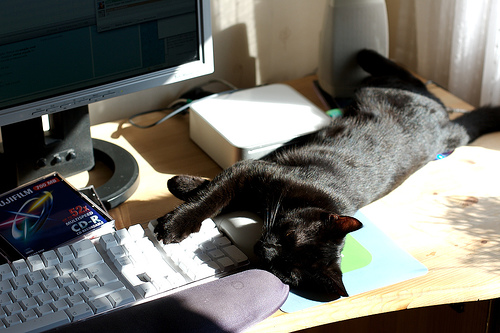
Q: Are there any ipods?
A: No, there are no ipods.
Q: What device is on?
A: The device is a monitor.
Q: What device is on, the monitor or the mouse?
A: The monitor is on.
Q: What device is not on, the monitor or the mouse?
A: The mouse is not on.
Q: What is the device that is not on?
A: The device is a computer mouse.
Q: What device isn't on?
A: The device is a computer mouse.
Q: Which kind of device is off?
A: The device is a monitor.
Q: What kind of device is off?
A: The device is a monitor.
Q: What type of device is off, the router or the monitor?
A: The monitor is off.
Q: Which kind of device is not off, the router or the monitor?
A: The router is not off.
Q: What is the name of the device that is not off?
A: The device is a router.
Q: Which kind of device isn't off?
A: The device is a router.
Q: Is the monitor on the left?
A: Yes, the monitor is on the left of the image.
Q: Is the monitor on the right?
A: No, the monitor is on the left of the image.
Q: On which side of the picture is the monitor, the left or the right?
A: The monitor is on the left of the image.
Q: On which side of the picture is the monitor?
A: The monitor is on the left of the image.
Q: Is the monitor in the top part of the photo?
A: Yes, the monitor is in the top of the image.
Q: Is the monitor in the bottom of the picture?
A: No, the monitor is in the top of the image.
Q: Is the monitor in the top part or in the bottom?
A: The monitor is in the top of the image.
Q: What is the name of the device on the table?
A: The device is a monitor.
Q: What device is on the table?
A: The device is a monitor.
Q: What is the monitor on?
A: The monitor is on the table.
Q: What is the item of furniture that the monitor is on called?
A: The piece of furniture is a table.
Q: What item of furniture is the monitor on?
A: The monitor is on the table.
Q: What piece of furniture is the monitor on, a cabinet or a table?
A: The monitor is on a table.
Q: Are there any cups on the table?
A: No, there is a monitor on the table.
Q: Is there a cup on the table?
A: No, there is a monitor on the table.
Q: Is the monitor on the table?
A: Yes, the monitor is on the table.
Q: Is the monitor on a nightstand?
A: No, the monitor is on the table.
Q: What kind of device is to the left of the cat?
A: The device is a monitor.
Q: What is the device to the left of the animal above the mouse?
A: The device is a monitor.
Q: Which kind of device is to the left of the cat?
A: The device is a monitor.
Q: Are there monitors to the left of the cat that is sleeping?
A: Yes, there is a monitor to the left of the cat.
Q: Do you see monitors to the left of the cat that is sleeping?
A: Yes, there is a monitor to the left of the cat.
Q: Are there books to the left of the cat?
A: No, there is a monitor to the left of the cat.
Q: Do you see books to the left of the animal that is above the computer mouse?
A: No, there is a monitor to the left of the cat.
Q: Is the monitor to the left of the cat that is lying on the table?
A: Yes, the monitor is to the left of the cat.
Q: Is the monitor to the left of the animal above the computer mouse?
A: Yes, the monitor is to the left of the cat.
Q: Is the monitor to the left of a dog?
A: No, the monitor is to the left of the cat.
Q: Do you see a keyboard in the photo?
A: Yes, there is a keyboard.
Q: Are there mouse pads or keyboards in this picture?
A: Yes, there is a keyboard.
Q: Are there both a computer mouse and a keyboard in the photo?
A: Yes, there are both a keyboard and a computer mouse.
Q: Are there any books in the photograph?
A: No, there are no books.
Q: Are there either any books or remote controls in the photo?
A: No, there are no books or remote controls.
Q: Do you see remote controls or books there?
A: No, there are no books or remote controls.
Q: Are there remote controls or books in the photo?
A: No, there are no books or remote controls.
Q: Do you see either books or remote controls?
A: No, there are no books or remote controls.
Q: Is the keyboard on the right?
A: No, the keyboard is on the left of the image.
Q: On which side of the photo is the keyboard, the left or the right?
A: The keyboard is on the left of the image.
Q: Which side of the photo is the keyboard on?
A: The keyboard is on the left of the image.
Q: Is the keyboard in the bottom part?
A: Yes, the keyboard is in the bottom of the image.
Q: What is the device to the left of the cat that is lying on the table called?
A: The device is a keyboard.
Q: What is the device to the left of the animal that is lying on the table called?
A: The device is a keyboard.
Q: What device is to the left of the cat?
A: The device is a keyboard.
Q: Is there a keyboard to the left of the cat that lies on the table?
A: Yes, there is a keyboard to the left of the cat.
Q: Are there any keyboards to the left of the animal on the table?
A: Yes, there is a keyboard to the left of the cat.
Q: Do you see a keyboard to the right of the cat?
A: No, the keyboard is to the left of the cat.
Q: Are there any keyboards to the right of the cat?
A: No, the keyboard is to the left of the cat.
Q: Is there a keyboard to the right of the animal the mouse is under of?
A: No, the keyboard is to the left of the cat.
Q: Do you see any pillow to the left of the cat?
A: No, there is a keyboard to the left of the cat.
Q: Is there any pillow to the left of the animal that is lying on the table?
A: No, there is a keyboard to the left of the cat.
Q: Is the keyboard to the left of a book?
A: No, the keyboard is to the left of the cat.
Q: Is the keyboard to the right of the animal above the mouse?
A: No, the keyboard is to the left of the cat.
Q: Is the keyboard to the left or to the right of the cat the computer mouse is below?
A: The keyboard is to the left of the cat.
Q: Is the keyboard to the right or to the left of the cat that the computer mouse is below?
A: The keyboard is to the left of the cat.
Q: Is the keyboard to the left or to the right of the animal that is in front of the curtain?
A: The keyboard is to the left of the cat.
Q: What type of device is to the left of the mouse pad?
A: The device is a keyboard.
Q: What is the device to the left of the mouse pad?
A: The device is a keyboard.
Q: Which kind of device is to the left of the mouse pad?
A: The device is a keyboard.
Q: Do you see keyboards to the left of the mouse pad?
A: Yes, there is a keyboard to the left of the mouse pad.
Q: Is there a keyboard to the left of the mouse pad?
A: Yes, there is a keyboard to the left of the mouse pad.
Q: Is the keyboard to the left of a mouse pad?
A: Yes, the keyboard is to the left of a mouse pad.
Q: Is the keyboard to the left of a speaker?
A: No, the keyboard is to the left of a mouse pad.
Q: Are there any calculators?
A: No, there are no calculators.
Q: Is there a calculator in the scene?
A: No, there are no calculators.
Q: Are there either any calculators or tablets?
A: No, there are no calculators or tablets.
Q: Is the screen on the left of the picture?
A: Yes, the screen is on the left of the image.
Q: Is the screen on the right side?
A: No, the screen is on the left of the image.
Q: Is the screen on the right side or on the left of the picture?
A: The screen is on the left of the image.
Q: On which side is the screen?
A: The screen is on the left of the image.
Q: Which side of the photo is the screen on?
A: The screen is on the left of the image.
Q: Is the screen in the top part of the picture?
A: Yes, the screen is in the top of the image.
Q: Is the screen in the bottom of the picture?
A: No, the screen is in the top of the image.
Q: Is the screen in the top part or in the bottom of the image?
A: The screen is in the top of the image.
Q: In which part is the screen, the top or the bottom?
A: The screen is in the top of the image.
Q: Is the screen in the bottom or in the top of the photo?
A: The screen is in the top of the image.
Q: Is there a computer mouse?
A: Yes, there is a computer mouse.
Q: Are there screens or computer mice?
A: Yes, there is a computer mouse.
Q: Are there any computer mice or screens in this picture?
A: Yes, there is a computer mouse.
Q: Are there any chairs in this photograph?
A: No, there are no chairs.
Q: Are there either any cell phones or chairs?
A: No, there are no chairs or cell phones.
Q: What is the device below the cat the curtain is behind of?
A: The device is a computer mouse.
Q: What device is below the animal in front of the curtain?
A: The device is a computer mouse.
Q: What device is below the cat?
A: The device is a computer mouse.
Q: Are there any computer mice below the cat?
A: Yes, there is a computer mouse below the cat.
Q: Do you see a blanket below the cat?
A: No, there is a computer mouse below the cat.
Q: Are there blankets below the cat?
A: No, there is a computer mouse below the cat.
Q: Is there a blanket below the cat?
A: No, there is a computer mouse below the cat.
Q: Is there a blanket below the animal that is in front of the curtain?
A: No, there is a computer mouse below the cat.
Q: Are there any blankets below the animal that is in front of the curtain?
A: No, there is a computer mouse below the cat.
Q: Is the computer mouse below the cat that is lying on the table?
A: Yes, the computer mouse is below the cat.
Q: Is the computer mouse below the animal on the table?
A: Yes, the computer mouse is below the cat.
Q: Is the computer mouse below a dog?
A: No, the computer mouse is below the cat.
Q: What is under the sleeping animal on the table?
A: The computer mouse is under the cat.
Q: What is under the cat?
A: The computer mouse is under the cat.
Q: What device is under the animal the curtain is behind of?
A: The device is a computer mouse.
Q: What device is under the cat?
A: The device is a computer mouse.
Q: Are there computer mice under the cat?
A: Yes, there is a computer mouse under the cat.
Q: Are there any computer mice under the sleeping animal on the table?
A: Yes, there is a computer mouse under the cat.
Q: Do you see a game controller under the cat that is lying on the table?
A: No, there is a computer mouse under the cat.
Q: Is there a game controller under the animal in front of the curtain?
A: No, there is a computer mouse under the cat.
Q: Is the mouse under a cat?
A: Yes, the mouse is under a cat.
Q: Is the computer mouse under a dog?
A: No, the computer mouse is under a cat.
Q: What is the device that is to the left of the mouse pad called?
A: The device is a computer mouse.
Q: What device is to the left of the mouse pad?
A: The device is a computer mouse.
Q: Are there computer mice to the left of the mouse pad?
A: Yes, there is a computer mouse to the left of the mouse pad.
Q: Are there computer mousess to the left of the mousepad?
A: No, there is a computer mouse to the left of the mousepad.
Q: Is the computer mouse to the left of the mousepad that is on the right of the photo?
A: Yes, the computer mouse is to the left of the mouse pad.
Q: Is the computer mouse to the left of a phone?
A: No, the computer mouse is to the left of the mouse pad.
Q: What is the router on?
A: The router is on the table.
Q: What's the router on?
A: The router is on the table.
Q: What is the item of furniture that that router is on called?
A: The piece of furniture is a table.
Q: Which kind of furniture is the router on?
A: The router is on the table.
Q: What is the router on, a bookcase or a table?
A: The router is on a table.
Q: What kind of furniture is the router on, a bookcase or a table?
A: The router is on a table.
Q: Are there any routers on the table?
A: Yes, there is a router on the table.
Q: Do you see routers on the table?
A: Yes, there is a router on the table.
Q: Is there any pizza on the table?
A: No, there is a router on the table.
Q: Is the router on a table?
A: Yes, the router is on a table.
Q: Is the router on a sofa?
A: No, the router is on a table.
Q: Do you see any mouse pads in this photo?
A: Yes, there is a mouse pad.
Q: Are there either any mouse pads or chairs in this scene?
A: Yes, there is a mouse pad.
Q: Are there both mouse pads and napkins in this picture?
A: No, there is a mouse pad but no napkins.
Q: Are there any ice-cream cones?
A: No, there are no ice-cream cones.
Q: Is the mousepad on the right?
A: Yes, the mousepad is on the right of the image.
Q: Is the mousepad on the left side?
A: No, the mousepad is on the right of the image.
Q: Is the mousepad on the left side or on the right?
A: The mousepad is on the right of the image.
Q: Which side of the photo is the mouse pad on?
A: The mouse pad is on the right of the image.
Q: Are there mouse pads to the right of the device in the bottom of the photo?
A: Yes, there is a mouse pad to the right of the keyboard.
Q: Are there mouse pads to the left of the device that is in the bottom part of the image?
A: No, the mouse pad is to the right of the keyboard.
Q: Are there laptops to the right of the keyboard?
A: No, there is a mouse pad to the right of the keyboard.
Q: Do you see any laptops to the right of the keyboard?
A: No, there is a mouse pad to the right of the keyboard.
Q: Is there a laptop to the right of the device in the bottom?
A: No, there is a mouse pad to the right of the keyboard.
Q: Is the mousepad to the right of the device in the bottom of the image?
A: Yes, the mousepad is to the right of the keyboard.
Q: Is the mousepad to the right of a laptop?
A: No, the mousepad is to the right of the keyboard.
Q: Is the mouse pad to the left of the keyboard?
A: No, the mouse pad is to the right of the keyboard.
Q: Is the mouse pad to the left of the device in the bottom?
A: No, the mouse pad is to the right of the keyboard.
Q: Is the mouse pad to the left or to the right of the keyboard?
A: The mouse pad is to the right of the keyboard.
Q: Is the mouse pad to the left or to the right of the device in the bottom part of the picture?
A: The mouse pad is to the right of the keyboard.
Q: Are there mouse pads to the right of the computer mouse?
A: Yes, there is a mouse pad to the right of the computer mouse.